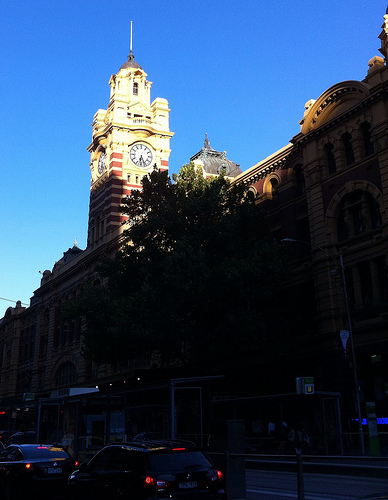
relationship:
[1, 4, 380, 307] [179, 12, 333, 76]
view of sky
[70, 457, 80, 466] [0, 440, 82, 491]
side mirror on black car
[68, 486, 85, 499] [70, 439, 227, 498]
wheel on car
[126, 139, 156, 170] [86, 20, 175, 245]
clock on tower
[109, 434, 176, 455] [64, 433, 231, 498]
roof of a car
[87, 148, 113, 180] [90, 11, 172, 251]
clock on tower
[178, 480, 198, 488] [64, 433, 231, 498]
license plate of a car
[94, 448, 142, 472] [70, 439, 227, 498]
window of a car